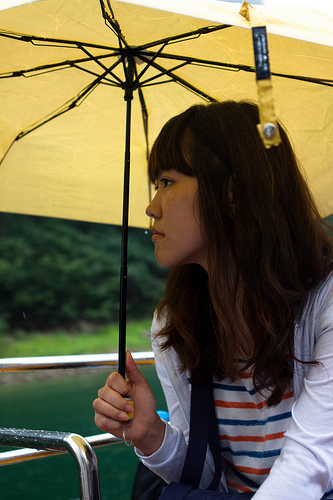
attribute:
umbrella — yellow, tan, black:
[2, 1, 331, 232]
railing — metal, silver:
[0, 349, 155, 500]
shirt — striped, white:
[133, 272, 329, 500]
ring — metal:
[118, 424, 135, 447]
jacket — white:
[133, 268, 332, 498]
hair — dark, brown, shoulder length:
[147, 100, 331, 407]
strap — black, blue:
[179, 361, 210, 493]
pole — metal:
[115, 96, 134, 404]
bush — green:
[1, 214, 167, 337]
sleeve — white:
[247, 332, 332, 499]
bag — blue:
[131, 463, 259, 498]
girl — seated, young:
[93, 98, 331, 491]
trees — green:
[1, 215, 165, 336]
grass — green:
[0, 319, 151, 358]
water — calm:
[3, 365, 167, 498]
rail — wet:
[0, 428, 100, 500]